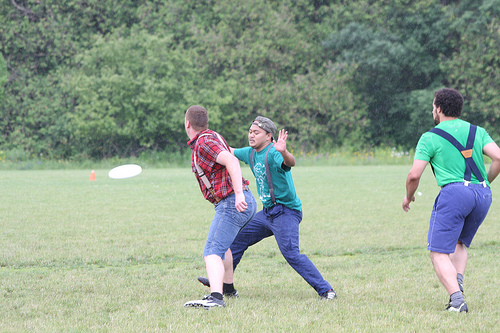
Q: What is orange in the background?
A: Cone.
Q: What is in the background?
A: Trees.